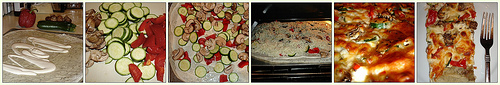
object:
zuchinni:
[105, 41, 127, 60]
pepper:
[249, 21, 331, 62]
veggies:
[191, 65, 207, 77]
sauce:
[168, 2, 249, 82]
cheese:
[351, 66, 368, 83]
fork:
[479, 11, 495, 83]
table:
[0, 12, 85, 34]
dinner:
[425, 3, 476, 83]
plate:
[417, 2, 496, 83]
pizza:
[252, 20, 331, 64]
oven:
[252, 1, 331, 82]